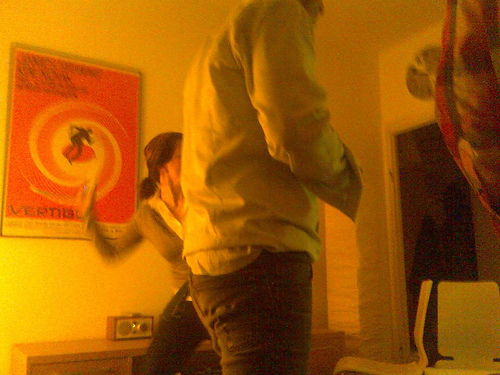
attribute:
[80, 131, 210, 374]
woman — active, playing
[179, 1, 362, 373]
man — playing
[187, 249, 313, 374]
jeans — blue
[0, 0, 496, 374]
wall — yellow, smooth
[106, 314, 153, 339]
radio — small, old styled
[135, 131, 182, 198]
hair — brown, pony tail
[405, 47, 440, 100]
clock — silver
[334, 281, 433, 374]
chair — white, unoccupied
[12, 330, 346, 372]
cabinet — wood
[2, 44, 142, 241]
poster — red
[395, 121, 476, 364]
door — open, framed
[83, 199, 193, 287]
sweater — gray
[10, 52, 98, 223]
letters — black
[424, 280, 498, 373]
chair — white, unoccupied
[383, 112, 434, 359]
frame — white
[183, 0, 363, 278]
shirt — long sleeved